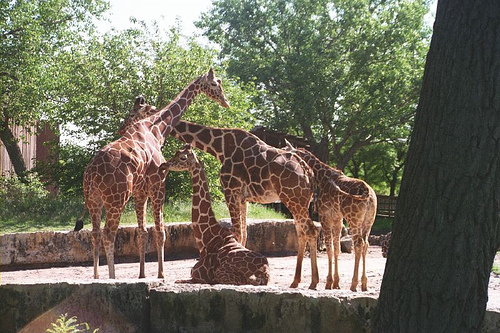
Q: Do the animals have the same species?
A: Yes, all the animals are giraffes.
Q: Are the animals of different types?
A: No, all the animals are giraffes.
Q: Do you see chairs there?
A: No, there are no chairs.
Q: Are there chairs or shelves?
A: No, there are no chairs or shelves.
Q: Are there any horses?
A: No, there are no horses.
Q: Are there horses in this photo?
A: No, there are no horses.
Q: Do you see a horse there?
A: No, there are no horses.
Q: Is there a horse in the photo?
A: No, there are no horses.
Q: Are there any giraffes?
A: Yes, there is a giraffe.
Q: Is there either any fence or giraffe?
A: Yes, there is a giraffe.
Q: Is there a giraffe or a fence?
A: Yes, there is a giraffe.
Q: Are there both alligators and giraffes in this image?
A: No, there is a giraffe but no alligators.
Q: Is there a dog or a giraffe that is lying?
A: Yes, the giraffe is lying.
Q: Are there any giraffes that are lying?
A: Yes, there is a giraffe that is lying.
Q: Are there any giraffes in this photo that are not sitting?
A: Yes, there is a giraffe that is lying.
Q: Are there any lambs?
A: No, there are no lambs.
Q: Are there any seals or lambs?
A: No, there are no lambs or seals.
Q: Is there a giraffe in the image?
A: Yes, there is a giraffe.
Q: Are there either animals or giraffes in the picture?
A: Yes, there is a giraffe.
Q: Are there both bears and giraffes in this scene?
A: No, there is a giraffe but no bears.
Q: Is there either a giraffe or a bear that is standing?
A: Yes, the giraffe is standing.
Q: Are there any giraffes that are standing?
A: Yes, there is a giraffe that is standing.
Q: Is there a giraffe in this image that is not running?
A: Yes, there is a giraffe that is standing.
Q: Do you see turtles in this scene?
A: No, there are no turtles.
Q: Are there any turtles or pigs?
A: No, there are no turtles or pigs.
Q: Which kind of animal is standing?
A: The animal is a giraffe.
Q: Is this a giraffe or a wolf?
A: This is a giraffe.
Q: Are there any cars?
A: No, there are no cars.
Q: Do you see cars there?
A: No, there are no cars.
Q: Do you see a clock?
A: No, there are no clocks.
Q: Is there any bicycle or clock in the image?
A: No, there are no clocks or bicycles.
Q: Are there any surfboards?
A: No, there are no surfboards.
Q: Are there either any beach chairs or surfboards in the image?
A: No, there are no surfboards or beach chairs.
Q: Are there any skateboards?
A: No, there are no skateboards.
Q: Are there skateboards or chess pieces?
A: No, there are no skateboards or chess pieces.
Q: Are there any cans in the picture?
A: No, there are no cans.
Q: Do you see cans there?
A: No, there are no cans.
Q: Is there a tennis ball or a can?
A: No, there are no cans or tennis balls.